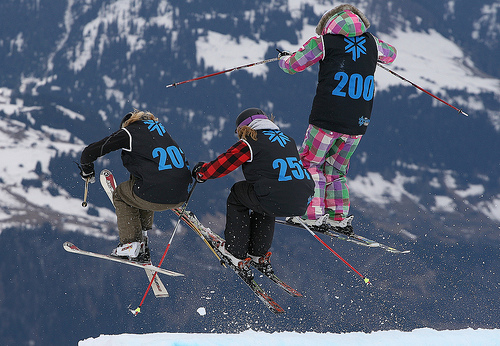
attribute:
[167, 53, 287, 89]
pole — red, silver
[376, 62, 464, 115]
pole — silver, red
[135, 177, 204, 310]
pole — red, silver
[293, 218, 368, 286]
pole — red, silver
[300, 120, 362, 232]
pants — plaid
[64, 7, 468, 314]
skier — skiing, jumping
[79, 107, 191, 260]
person — crouched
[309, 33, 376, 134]
vest — black, blue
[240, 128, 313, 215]
vest — black, blue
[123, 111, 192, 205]
vest — black, blue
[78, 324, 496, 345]
snow — white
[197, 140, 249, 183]
plaid — red, black, sleeve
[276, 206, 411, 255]
skis — black, brown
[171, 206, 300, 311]
skis — red, black, gray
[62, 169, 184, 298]
skis — white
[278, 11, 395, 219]
clothes — plaid, pink, green, checkered